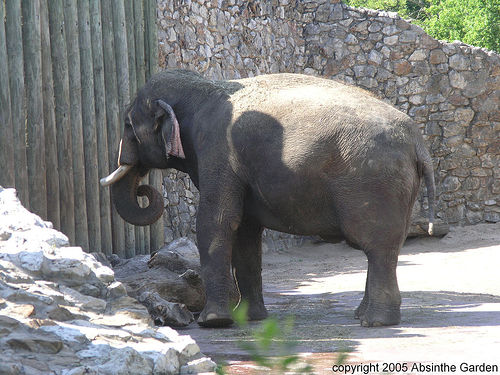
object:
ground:
[187, 289, 499, 374]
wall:
[438, 56, 498, 202]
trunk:
[99, 146, 163, 225]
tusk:
[98, 162, 130, 186]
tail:
[419, 159, 440, 236]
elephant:
[98, 69, 438, 327]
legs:
[360, 249, 400, 327]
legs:
[355, 271, 368, 320]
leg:
[231, 202, 263, 322]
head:
[99, 69, 197, 228]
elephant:
[94, 67, 447, 329]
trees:
[415, 0, 484, 46]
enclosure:
[74, 16, 419, 80]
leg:
[196, 194, 236, 325]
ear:
[151, 90, 185, 162]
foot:
[363, 304, 401, 326]